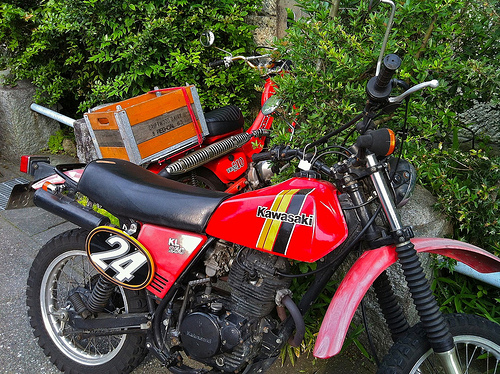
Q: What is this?
A: Bike.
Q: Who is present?
A: No one.